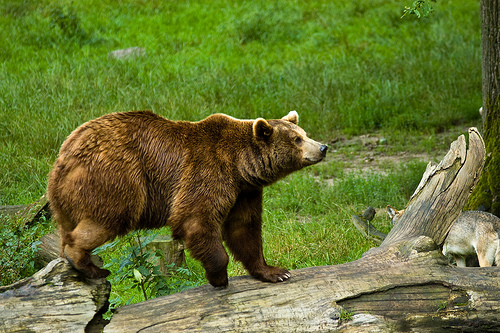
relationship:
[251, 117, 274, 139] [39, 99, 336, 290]
ear on bear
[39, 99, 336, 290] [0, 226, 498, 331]
bear on trunk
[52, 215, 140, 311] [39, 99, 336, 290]
leg of bear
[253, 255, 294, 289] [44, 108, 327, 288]
foot of bear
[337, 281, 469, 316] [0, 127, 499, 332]
hole in tree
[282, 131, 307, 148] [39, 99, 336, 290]
eye of bear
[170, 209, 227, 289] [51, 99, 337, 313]
right leg of bear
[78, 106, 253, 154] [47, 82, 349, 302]
back of bear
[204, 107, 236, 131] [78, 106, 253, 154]
hump on back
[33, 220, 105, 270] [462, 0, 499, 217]
stump of tree